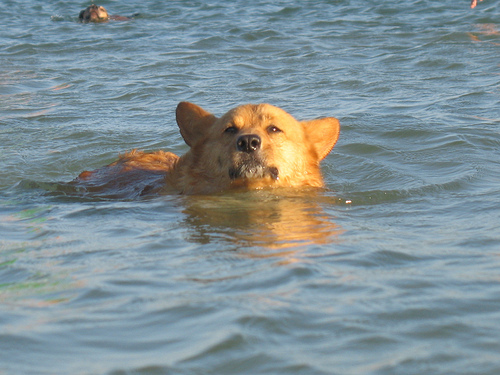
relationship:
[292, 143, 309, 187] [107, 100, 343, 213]
fur of dog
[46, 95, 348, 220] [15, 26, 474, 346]
dog in water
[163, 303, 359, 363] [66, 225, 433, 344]
ripples in water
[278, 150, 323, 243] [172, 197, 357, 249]
light on surface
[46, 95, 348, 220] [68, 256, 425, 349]
dog swimming water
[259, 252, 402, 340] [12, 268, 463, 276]
ripples in water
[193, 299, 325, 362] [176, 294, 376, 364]
ripples in water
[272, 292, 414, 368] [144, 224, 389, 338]
ripples in water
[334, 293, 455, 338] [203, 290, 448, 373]
ripples in water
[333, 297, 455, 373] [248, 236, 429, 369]
ripples in water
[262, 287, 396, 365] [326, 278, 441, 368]
ripples in water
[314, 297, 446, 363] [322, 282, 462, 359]
ripples in water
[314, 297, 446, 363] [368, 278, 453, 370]
ripples in water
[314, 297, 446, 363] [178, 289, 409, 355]
ripples in water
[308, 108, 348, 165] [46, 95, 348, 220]
ears of dog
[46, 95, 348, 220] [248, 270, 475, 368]
dog in water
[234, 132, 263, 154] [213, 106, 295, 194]
black nose on face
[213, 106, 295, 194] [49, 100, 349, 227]
face of dog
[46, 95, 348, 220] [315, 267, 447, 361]
dog in water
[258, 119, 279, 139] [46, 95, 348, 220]
eyes on dog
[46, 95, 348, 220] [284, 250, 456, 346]
dog swimming water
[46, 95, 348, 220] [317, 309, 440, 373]
dog in water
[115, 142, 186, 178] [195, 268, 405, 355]
back in water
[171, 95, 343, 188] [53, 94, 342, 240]
head of dog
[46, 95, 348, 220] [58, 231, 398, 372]
dog in water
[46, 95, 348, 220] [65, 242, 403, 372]
dog swimming in water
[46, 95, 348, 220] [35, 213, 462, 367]
dog treading in water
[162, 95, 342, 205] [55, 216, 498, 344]
head above water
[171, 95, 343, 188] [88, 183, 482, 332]
head above surface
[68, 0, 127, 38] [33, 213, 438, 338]
dog in water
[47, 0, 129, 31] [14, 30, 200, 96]
dog treading water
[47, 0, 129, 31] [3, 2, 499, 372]
dog swimming in water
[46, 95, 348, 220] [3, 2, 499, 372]
dog swimming in water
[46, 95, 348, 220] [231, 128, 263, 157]
dog has black nose